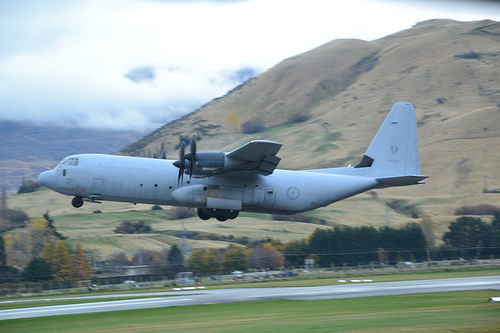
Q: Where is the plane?
A: In the air.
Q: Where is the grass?
A: On the ground.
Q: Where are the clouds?
A: In the sky.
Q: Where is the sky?
A: Above the mountain.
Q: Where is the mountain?
A: Behind the plane.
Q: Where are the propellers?
A: On the plane.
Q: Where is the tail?
A: On the plane.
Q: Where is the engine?
A: On the plane.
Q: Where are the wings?
A: On the plane.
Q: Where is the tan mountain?
A: On side of plane.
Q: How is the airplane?
A: It is taking off.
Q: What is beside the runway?
A: Some trees.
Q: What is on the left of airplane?
A: A wing.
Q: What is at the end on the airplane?
A: The tail end.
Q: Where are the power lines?
A: On side of the air strip.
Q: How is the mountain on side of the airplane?
A: It is bare.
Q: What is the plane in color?
A: Grey.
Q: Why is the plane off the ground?
A: It is taking off.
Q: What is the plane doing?
A: Taking off.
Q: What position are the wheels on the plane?
A: Down.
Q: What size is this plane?
A: Large.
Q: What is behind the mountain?
A: Clouds.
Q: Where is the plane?
A: In the air.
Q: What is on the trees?
A: Leaves.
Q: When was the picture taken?
A: During the day.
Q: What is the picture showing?
A: An airplane.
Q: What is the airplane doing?
A: Flying in the air.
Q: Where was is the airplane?
A: In the air.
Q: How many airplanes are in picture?
A: One.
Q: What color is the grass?
A: Green.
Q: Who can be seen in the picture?
A: No one.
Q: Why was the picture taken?
A: To capture the airplane.